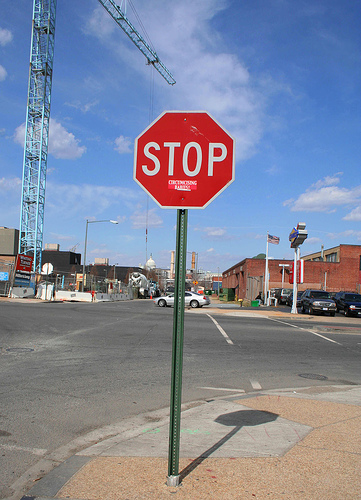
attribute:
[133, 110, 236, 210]
sign — red, white, octagon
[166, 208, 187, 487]
pole — metal, green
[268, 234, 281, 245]
flag — waving, american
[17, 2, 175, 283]
crane — metal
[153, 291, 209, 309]
car — silver, grey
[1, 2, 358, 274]
sky — blue, clear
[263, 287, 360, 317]
cars — parked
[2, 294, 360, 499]
street — grey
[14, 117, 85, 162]
cloud — white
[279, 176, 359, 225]
cloud — white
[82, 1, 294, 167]
cloud — white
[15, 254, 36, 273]
sign — red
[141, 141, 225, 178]
letters — white